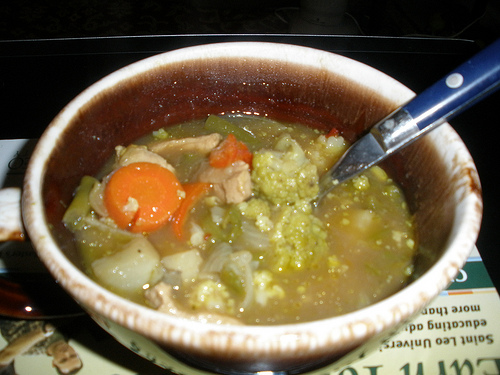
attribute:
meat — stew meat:
[205, 162, 252, 204]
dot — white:
[420, 63, 498, 117]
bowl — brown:
[7, 29, 491, 374]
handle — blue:
[409, 40, 498, 135]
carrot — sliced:
[109, 135, 253, 245]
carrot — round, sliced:
[96, 160, 189, 238]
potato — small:
[93, 236, 163, 291]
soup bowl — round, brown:
[21, 33, 485, 372]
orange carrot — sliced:
[101, 160, 186, 235]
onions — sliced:
[205, 212, 267, 301]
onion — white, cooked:
[202, 240, 234, 274]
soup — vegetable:
[65, 108, 411, 328]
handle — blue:
[400, 50, 499, 132]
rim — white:
[22, 41, 481, 358]